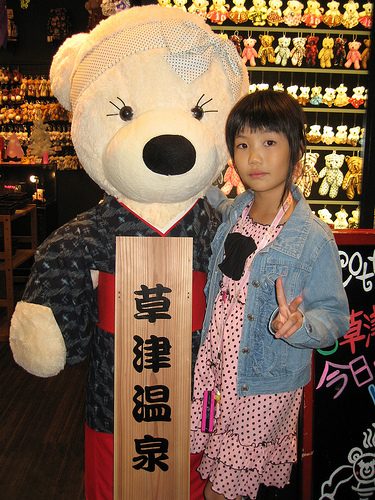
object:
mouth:
[247, 167, 270, 179]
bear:
[357, 0, 373, 31]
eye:
[261, 138, 277, 150]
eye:
[235, 141, 250, 152]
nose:
[247, 151, 263, 167]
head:
[225, 90, 305, 191]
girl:
[190, 90, 350, 498]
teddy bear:
[288, 35, 308, 70]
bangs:
[230, 95, 286, 137]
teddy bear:
[342, 39, 361, 71]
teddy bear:
[330, 36, 346, 69]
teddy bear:
[314, 150, 345, 201]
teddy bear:
[358, 40, 372, 70]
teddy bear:
[345, 85, 364, 110]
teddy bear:
[254, 34, 275, 66]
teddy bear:
[340, 152, 361, 201]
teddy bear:
[293, 151, 318, 200]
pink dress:
[186, 198, 305, 498]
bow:
[216, 231, 258, 283]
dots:
[261, 225, 265, 231]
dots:
[230, 281, 232, 287]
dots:
[244, 228, 248, 237]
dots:
[223, 322, 228, 326]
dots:
[210, 327, 214, 333]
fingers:
[272, 277, 287, 306]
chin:
[247, 182, 269, 197]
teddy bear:
[308, 85, 322, 107]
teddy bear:
[239, 36, 257, 68]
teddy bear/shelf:
[205, 25, 370, 42]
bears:
[9, 0, 252, 498]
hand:
[267, 278, 303, 340]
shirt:
[19, 196, 228, 436]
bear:
[8, 3, 251, 498]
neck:
[251, 181, 287, 209]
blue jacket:
[196, 184, 348, 397]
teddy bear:
[331, 207, 348, 233]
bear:
[320, 0, 341, 31]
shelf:
[209, 24, 370, 38]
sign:
[268, 276, 303, 339]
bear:
[338, 0, 360, 32]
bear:
[279, 0, 304, 30]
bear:
[300, 0, 321, 31]